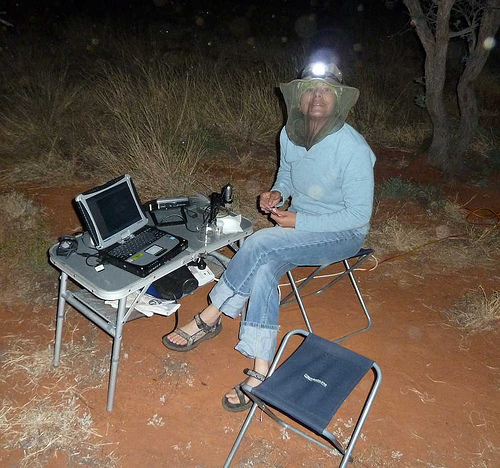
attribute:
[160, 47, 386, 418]
woman — sitting, interesting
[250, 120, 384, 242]
shirt — blue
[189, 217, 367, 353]
jeans — blue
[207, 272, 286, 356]
cuffs — folded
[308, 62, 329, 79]
light — on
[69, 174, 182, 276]
laptop — protected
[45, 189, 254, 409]
table — metal, small, foldable, grey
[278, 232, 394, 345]
chair — small, metal, canvas, blue, foldable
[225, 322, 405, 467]
chair — small, metal, canvas, blue, foldable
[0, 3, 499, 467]
outside — dark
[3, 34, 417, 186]
grass — patchy, tall, dried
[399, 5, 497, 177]
tree — scary, small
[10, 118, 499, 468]
clearing — small